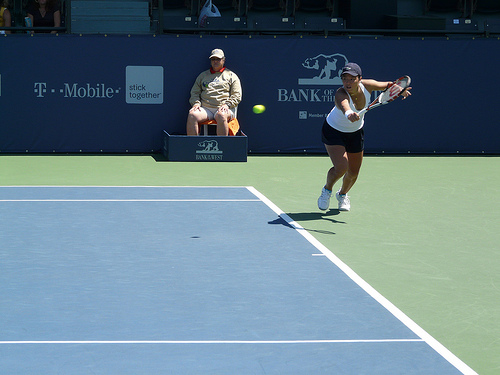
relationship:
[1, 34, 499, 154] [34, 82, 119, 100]
wall has an banner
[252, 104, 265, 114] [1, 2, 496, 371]
ball in air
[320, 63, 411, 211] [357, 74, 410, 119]
lady has a racket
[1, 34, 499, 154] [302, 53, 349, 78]
wall has a bear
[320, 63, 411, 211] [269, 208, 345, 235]
lady has a shadow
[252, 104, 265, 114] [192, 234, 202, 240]
ball has a reflection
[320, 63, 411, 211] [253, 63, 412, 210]
lady playing tennis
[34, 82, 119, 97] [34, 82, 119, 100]
banner has a banner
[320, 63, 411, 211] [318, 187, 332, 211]
lady has feet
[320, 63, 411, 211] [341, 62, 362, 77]
lady has a hat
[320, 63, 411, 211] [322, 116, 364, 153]
lady wearing shorts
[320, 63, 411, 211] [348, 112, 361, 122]
lady has hands